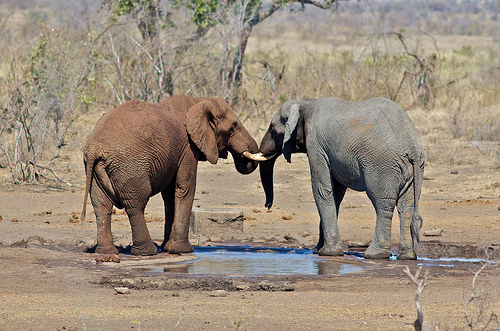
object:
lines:
[175, 149, 192, 170]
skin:
[120, 112, 181, 178]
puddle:
[102, 236, 495, 293]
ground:
[0, 136, 499, 330]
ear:
[280, 104, 299, 166]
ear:
[183, 100, 223, 166]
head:
[254, 99, 306, 166]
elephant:
[256, 94, 423, 261]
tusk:
[241, 151, 275, 163]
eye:
[227, 121, 243, 128]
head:
[184, 97, 259, 175]